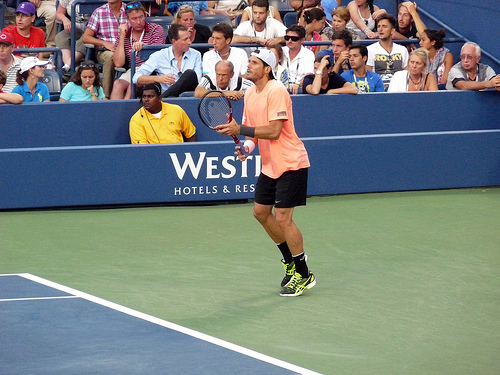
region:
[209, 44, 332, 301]
A male tennis player.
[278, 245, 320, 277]
Man wearing dark Nike socks.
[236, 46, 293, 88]
The player is wearing his white cap backwards.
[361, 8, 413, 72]
Man wearing a white Rocky shirt.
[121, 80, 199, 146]
Man in a yellow shirt.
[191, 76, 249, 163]
A racket in a hand.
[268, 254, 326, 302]
Gray shoes with yellow laces.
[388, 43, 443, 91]
Woman wearing necklace in stands.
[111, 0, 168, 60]
Man in striped shirt.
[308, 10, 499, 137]
Group of fans watching ball.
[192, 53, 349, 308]
male tennis player playing tennis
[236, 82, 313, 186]
man wearing orange shirt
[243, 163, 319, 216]
man wearing black shorts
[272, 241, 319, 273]
man wearing black socks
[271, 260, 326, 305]
man wearing black, yellow and white shoes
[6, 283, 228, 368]
blue and white tennis court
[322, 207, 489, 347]
green area behind tennis court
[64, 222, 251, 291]
green area next to tennis court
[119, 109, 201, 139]
male security guard wearing yellow shirt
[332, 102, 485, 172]
blue wall near tennis court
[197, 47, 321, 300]
a man standing by the edge of the tennis court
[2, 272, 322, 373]
the end of the blue tennis court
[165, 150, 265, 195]
the writing on the wall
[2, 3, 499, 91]
the audience watching the tennis match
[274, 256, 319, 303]
the tennis shoes the man is wearing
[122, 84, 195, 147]
a man with some headphones on his head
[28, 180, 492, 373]
the green part of the tennis court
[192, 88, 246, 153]
the tennis racket the man is holding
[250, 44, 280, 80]
the white hat on the man's head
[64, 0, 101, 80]
part of the metal railing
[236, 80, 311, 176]
An orange shirt on a man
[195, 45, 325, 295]
A tennis player with black shorts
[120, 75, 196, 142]
A guy wearing yellow shirt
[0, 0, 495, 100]
A group of people watching tennis game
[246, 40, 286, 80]
A white hat on a tennis player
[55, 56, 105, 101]
A woman with blue shirt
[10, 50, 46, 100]
A woman with white hat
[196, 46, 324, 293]
A tennis player in a game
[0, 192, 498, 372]
green floor of a tennis court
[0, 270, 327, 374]
White lines on the tennis court floor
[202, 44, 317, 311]
A male tennis player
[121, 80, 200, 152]
A black man in a yellow shirt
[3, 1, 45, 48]
A man in a purple cap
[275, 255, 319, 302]
Sneakers with yellow laces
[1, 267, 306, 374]
The edge of the tennis court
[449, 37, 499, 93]
A man looking bored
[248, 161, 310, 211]
A pair of black shorts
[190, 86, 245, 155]
Red tennis racket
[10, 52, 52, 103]
A woman in a blue shirt looking to the right.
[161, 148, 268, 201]
A hotel advertisement